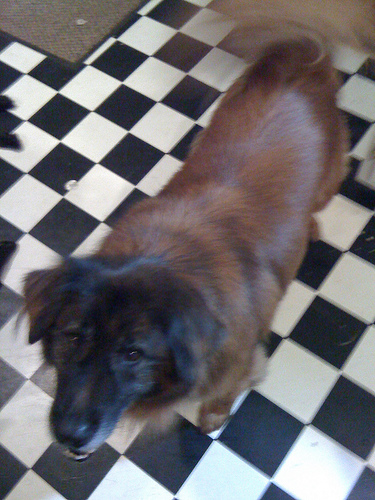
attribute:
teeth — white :
[53, 441, 92, 464]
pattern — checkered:
[61, 109, 166, 178]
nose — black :
[50, 410, 101, 448]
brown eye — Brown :
[121, 345, 145, 363]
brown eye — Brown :
[60, 328, 87, 347]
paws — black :
[0, 102, 19, 151]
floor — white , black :
[271, 347, 372, 497]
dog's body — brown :
[26, 164, 345, 261]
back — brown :
[112, 69, 330, 297]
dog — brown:
[34, 32, 341, 419]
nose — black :
[51, 411, 98, 443]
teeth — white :
[60, 446, 87, 459]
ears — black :
[24, 255, 227, 384]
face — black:
[35, 302, 167, 460]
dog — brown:
[24, 18, 323, 479]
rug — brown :
[1, 2, 150, 77]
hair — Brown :
[41, 44, 358, 466]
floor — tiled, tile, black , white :
[0, 0, 371, 499]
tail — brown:
[221, 0, 359, 54]